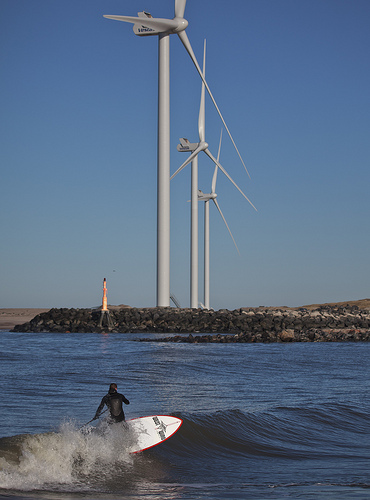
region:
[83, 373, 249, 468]
surfer with paddle on wide board on a wave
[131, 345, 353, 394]
uneven surface of moving water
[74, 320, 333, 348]
outcrop of rocks forming jetty into the water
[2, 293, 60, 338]
large rocks contrasted with sand along the water's edge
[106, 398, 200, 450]
white surfboard with centered design and writing with red edge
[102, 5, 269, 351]
wind turbines pointing to sky, sea and land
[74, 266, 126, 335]
upright orange structure on rocks at edge of water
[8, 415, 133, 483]
water splashing and becoming many smaller droplets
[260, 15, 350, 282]
clear, cloudless sky in varying shades of blue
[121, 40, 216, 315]
thick, sturdy metallic poles supporting the moving parts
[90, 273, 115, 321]
a light house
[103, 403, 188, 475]
a surf board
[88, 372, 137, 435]
a surfer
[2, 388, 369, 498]
a wave in the ocean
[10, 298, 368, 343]
a rock shore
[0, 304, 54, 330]
a small foothill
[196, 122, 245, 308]
a large windmill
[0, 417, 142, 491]
a foamy wave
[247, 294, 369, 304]
a small foothill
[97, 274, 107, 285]
the top of a lighthouse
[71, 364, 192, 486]
Man paddling board.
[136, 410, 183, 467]
White board with red trim.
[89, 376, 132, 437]
Man in black wet suit.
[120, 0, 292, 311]
Tall wind turbines.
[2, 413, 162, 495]
White water behind man paddling board.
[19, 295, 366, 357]
Black rocks on beach.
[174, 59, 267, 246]
Grey turbine propellers.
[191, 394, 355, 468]
Swelling wave on water.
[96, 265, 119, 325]
Edifice near rocks.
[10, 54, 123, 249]
Deep, blue sky without clouds.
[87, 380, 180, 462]
There is a surfboard.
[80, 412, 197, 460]
The surfboard is red and white.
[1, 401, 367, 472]
The water creates waves.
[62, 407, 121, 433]
The surfer has a paddle.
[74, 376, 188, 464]
The surfer is riding the wave.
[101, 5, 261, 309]
There are three wind turbines.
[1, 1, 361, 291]
The sky is blue.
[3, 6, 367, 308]
The sky is clear.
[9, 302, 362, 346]
There is a rocky pier.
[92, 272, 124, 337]
There is an orange light.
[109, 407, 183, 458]
red and white surfboard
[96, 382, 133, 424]
male surfer riding a wave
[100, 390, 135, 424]
black wet suit worn by male surfer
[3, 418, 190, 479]
ocean wave ridden by surfer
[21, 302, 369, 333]
rocky shoreline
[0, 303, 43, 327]
sandy beach in the background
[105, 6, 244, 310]
White wind turbines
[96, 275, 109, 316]
Small orange light house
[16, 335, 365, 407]
dark blue ocean water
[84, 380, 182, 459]
man on a surfboard riding a wave